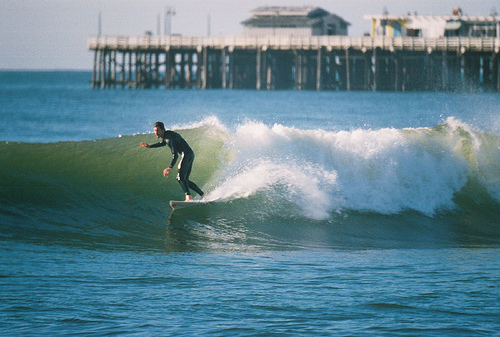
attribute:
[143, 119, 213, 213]
wetsuit — black 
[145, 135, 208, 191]
wetsuit — black 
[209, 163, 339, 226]
water — flying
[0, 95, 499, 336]
ocean — blue, white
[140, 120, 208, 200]
man — surfing, black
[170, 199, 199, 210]
surfboard — white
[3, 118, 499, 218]
wave — crashing, cresting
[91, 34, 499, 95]
pier — blurry, wooden